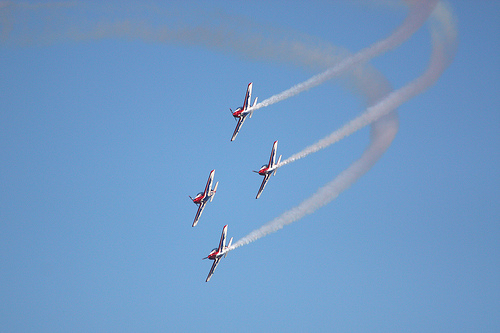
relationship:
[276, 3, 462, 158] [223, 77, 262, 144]
trail of airplane